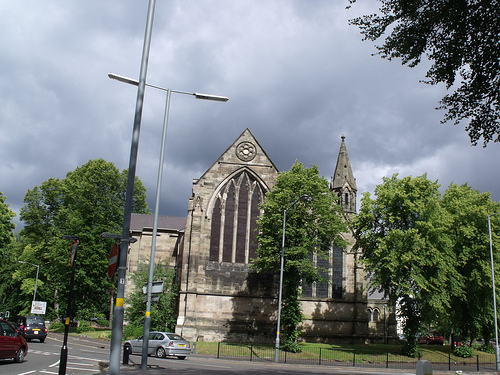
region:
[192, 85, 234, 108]
a white street light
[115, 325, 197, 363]
a gray car on the street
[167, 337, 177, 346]
the tail light of a car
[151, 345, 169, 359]
a black car tire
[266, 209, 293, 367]
a gray metal pole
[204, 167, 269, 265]
the windows on a church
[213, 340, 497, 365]
a small black fence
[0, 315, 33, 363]
a red car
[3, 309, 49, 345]
a black car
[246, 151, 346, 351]
a green tree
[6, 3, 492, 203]
The sky is blue.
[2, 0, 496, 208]
The sky is cloudy.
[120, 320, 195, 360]
The car is silver.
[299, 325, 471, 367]
The grass is green.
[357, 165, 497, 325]
The trees are green.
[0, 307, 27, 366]
The van is red.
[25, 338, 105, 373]
The lines are white.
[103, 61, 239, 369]
Light post on side of street.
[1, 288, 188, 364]
Three cars at intersection.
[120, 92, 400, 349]
the building is stone.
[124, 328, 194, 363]
silver car on road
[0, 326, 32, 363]
red vehicle on road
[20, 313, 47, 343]
black car on road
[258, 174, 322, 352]
tall green tree in front of church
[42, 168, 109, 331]
green tree on side of church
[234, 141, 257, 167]
ornate circle on top of church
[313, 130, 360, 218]
pointed steeple on top of church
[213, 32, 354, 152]
dark rain clouds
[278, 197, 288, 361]
tall metal pole in front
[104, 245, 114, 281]
red caution sign on road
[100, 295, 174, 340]
Yellow stripes on tall poles.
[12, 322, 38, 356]
Red car driving in road.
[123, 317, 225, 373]
Gray car driving in road.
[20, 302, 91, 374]
Black car driving in road.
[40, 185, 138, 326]
Green leaves on tree.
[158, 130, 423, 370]
Large church on the corner.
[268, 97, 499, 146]
Dark clouds in the sky.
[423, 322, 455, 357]
Red car parked near church.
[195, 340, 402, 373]
Dark fence near road.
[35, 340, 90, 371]
White lines marking the road.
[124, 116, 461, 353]
tall stone church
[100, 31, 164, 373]
tall grey metal light pole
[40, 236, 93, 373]
small brown pole with sign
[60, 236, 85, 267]
sign is white and red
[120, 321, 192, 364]
grey car on road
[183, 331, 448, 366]
black fence by road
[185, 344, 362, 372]
grey road by church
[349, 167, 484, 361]
green tree beside church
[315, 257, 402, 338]
shadow of trees on church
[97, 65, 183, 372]
tall pole with lights